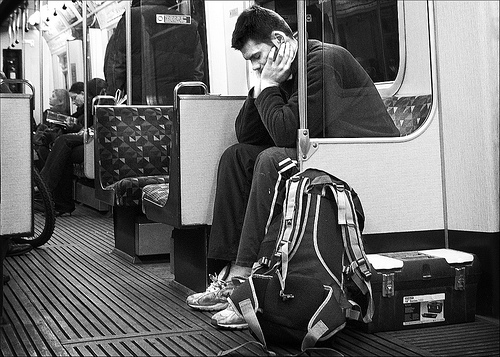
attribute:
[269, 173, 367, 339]
bag — tall, sitting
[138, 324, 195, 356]
floor — covered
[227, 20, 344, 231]
man — sleeping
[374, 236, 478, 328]
case — big, sitting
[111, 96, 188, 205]
seat — empty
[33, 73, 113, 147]
people — sitting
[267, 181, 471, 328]
luggage — black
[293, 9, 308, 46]
pole — gray, metal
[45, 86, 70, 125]
woman — riding